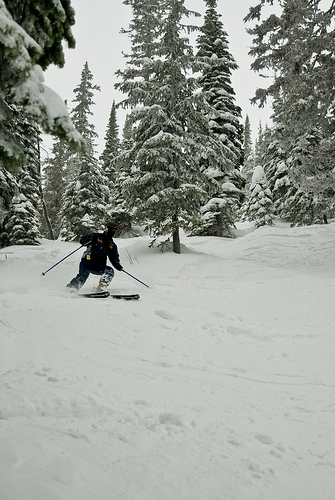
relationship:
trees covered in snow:
[239, 3, 324, 226] [12, 222, 324, 348]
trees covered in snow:
[112, 1, 249, 244] [12, 222, 324, 348]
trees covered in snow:
[50, 62, 131, 234] [12, 222, 324, 348]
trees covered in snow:
[0, 5, 58, 246] [12, 222, 324, 348]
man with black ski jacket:
[66, 222, 123, 292] [79, 232, 123, 272]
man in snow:
[66, 222, 123, 292] [179, 268, 285, 375]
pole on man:
[116, 263, 154, 291] [87, 223, 123, 292]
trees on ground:
[0, 0, 334, 253] [155, 248, 285, 424]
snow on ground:
[0, 263, 335, 500] [53, 309, 317, 465]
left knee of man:
[106, 265, 114, 277] [66, 222, 123, 292]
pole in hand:
[41, 242, 88, 278] [79, 236, 89, 246]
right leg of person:
[67, 257, 90, 291] [65, 221, 123, 297]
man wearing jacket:
[66, 222, 123, 292] [81, 235, 122, 268]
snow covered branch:
[0, 263, 335, 500] [192, 105, 228, 151]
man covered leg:
[69, 217, 124, 299] [94, 264, 112, 297]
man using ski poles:
[66, 222, 123, 292] [36, 234, 154, 289]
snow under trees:
[60, 314, 216, 377] [48, 9, 334, 229]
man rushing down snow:
[66, 222, 123, 292] [0, 263, 335, 500]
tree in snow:
[115, 0, 249, 255] [187, 313, 303, 391]